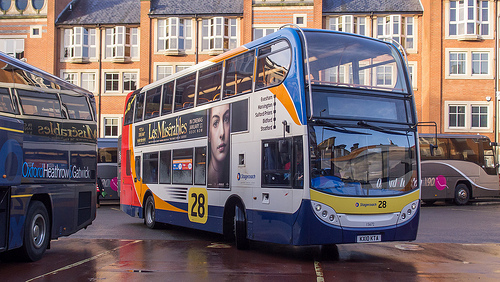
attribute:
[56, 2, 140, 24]
roof — shingled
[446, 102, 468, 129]
window — glass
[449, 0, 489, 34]
window — glass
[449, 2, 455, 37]
window — glass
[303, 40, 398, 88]
window — large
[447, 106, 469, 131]
window — glass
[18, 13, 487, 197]
building — red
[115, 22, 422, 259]
bus — large, blue, red, white, double level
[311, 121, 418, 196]
windshield — large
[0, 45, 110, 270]
bus — parked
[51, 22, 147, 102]
windows — several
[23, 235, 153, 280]
line — white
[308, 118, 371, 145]
wiper — windshield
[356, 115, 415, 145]
wiper — windshield